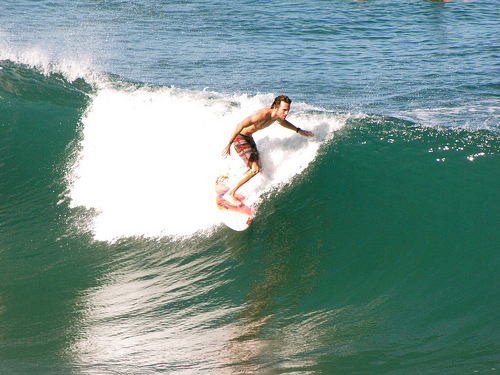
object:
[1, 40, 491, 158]
wave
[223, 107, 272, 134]
torso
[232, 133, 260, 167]
shorts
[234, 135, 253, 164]
stripe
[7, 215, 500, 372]
wave front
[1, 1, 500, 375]
water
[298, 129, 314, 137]
hand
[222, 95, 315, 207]
man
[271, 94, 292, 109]
hair